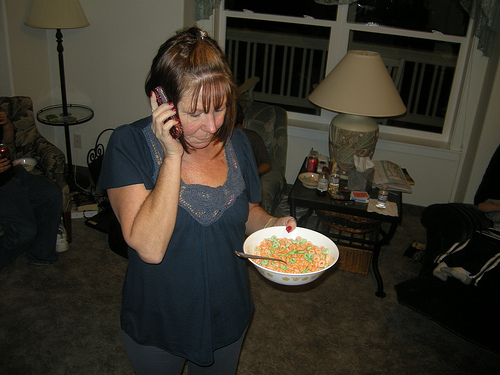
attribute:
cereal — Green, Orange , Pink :
[293, 237, 323, 264]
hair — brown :
[146, 18, 236, 139]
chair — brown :
[392, 198, 499, 337]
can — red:
[292, 152, 327, 179]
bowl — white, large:
[245, 223, 338, 288]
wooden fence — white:
[228, 27, 458, 129]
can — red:
[302, 149, 322, 171]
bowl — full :
[228, 215, 343, 287]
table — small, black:
[287, 152, 402, 297]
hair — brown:
[139, 22, 239, 161]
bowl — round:
[236, 223, 341, 291]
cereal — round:
[268, 241, 310, 269]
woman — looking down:
[83, 32, 335, 374]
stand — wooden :
[281, 143, 418, 303]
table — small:
[276, 150, 412, 287]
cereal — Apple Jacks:
[260, 235, 327, 272]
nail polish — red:
[286, 223, 295, 233]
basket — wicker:
[320, 210, 379, 276]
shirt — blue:
[97, 144, 299, 362]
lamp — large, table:
[306, 48, 408, 181]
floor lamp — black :
[24, 9, 97, 216]